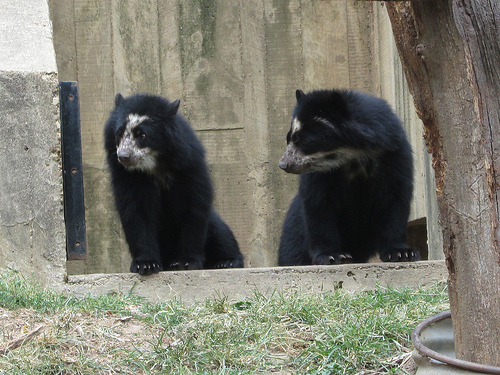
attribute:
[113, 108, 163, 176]
face — white, black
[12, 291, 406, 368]
grass — short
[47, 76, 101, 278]
metal — black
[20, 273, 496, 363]
ground — grey, cement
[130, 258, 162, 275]
furry — black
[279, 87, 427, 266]
animal — bear like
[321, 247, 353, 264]
animal paws — furry, black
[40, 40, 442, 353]
picture — outdoors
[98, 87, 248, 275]
animal — black, furry, white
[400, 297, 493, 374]
metal — green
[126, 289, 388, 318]
grass — short, green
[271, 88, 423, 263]
bear — black, small, furry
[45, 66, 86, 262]
pillar — concrete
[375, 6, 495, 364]
tree trunk — scarred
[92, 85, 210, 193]
animal — fluffy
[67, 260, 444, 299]
concrete wall — short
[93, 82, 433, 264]
bears — sitting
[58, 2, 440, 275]
door — large, wooden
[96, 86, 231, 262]
furry bear — black, small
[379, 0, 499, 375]
trunk — bare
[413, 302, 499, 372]
ring — thick, metal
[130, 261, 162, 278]
claws — sharp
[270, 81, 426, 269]
animal — black, furry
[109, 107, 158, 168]
patch — fur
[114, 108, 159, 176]
hair — white